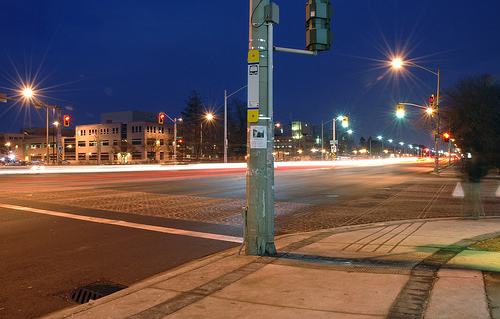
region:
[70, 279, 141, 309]
Man hole drain cover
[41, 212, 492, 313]
Sidewalk made of cement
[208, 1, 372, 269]
Pole holding traffic signals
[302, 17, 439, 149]
Street lights along the road way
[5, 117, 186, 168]
Row of buildings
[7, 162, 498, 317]
Road way without any cars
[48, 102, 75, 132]
Traffic light indciating for people to stop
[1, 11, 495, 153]
Completely clear dark blue sky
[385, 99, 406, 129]
Trafflic light indicating for people to go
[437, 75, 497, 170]
Tree in the midst of a city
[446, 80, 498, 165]
tree visible at distance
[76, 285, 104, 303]
drain vent at road side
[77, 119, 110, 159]
building visible at background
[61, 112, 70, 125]
signal panel hanging from pole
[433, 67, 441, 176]
lamp post installed at side of road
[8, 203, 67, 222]
white color line made on way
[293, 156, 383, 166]
rays of light falling on ground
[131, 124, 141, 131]
windows of the building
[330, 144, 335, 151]
sign board visible fixed to pole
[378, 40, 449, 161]
street light on a pole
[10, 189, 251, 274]
white lines in the road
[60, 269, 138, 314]
sewer in the road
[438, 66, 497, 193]
green tree on sidewalk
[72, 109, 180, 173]
buildings at a corner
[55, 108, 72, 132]
street light above road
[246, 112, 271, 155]
stickers on a pole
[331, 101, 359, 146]
green traffic lights on the road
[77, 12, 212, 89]
dark blue sky in the distance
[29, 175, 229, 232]
walkway in the street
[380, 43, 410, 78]
part of a light pole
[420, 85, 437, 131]
part of a stop light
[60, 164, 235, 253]
part of a cross walk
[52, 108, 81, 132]
part of a stop light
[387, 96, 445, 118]
part of a stop light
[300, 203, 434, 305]
part of a sidewalk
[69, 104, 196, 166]
large building in the background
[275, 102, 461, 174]
lots of street lights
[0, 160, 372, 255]
part of a cross walk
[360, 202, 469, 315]
part of a sidewalk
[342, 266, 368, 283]
part of a floor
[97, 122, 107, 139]
a window on the building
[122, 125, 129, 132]
a window on the building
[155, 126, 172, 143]
a window on the building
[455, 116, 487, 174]
green leaves on the tree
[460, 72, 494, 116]
green leaves on the tree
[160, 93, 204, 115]
green leaves on the tree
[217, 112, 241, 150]
green leaves on the tree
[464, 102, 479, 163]
green leaves on the tree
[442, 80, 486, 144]
green leaves on the tree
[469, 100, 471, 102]
A green leaf on a plant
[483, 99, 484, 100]
A green leaf on a plant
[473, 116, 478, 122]
A green leaf on a plant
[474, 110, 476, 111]
A green leaf on a plant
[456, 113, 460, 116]
A green leaf on a plant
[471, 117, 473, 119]
A green leaf on a plant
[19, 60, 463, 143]
Traffic lights above street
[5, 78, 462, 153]
Traffic lights above road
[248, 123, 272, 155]
Flyer on street pole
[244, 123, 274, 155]
Paper on street pole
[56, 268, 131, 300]
Drain on the curb